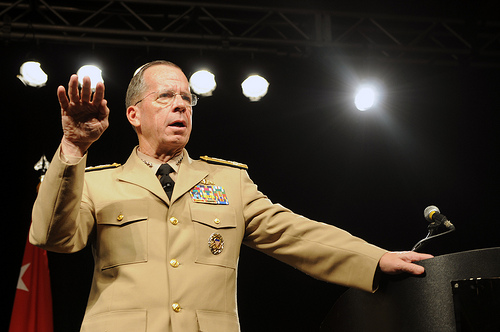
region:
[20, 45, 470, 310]
man in military uniform speaking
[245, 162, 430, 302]
arm extended to podium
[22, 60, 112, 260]
bent arm with palm showing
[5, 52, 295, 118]
row of circular white lights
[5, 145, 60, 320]
red flag with white design behind arm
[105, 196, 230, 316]
brass buttons on front of jacket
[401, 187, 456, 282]
microphone curled over podium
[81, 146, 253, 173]
epaulets across shoulders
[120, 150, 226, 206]
stars on collar above dark tie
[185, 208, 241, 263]
insignia on buttoned pocket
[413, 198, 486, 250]
Speaker attached to podium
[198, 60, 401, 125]
Lights shining down on speaker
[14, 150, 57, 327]
Red flag with white star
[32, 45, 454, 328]
Man standing next to black podium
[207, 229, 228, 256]
Badge on from of man's suit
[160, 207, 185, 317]
Gold buttons on man's suit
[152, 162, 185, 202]
Brown neck tie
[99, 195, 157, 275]
Pocket on man's suit with gold button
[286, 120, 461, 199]
Black backdrop behind speaker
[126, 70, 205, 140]
Man wearing pair of eyeglasses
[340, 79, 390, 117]
this is a light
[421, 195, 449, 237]
this is a microphone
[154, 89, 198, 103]
this is a spectacle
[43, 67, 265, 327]
this is a man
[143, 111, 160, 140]
the man has light skin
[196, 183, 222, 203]
this is a barge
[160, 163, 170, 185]
this is a neck tie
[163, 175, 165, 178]
the neck tie is black in color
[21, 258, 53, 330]
this is a flag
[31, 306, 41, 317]
the flag is red in color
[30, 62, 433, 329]
a man in uniform standing by a podium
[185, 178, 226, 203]
the assorted medals on the man's uniform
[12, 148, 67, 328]
the red flag behind the man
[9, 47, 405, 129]
a row of lights behind the man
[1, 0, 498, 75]
the metal railing above the lights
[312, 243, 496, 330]
the black podium on the stage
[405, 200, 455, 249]
the microphone on the podium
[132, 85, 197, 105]
the glasses on the man's face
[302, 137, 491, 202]
the black background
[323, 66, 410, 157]
a very shiny light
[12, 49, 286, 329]
this is a man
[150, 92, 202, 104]
the man is wearing spectacles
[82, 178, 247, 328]
the suit is brown in color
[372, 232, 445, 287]
the hand is on the pulpit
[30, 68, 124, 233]
the hand is on air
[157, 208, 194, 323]
the suit is buttoned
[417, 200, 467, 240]
these are two microphones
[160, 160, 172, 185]
this is neck tie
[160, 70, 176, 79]
the man is light skinned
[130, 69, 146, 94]
the hair is short